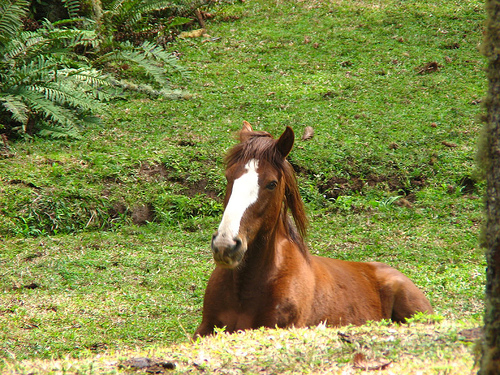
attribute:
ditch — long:
[85, 257, 494, 366]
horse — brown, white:
[172, 103, 437, 340]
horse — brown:
[196, 121, 428, 338]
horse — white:
[184, 116, 436, 340]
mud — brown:
[67, 195, 154, 236]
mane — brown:
[238, 130, 315, 250]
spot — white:
[210, 154, 259, 257]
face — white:
[195, 130, 301, 283]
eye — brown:
[260, 177, 281, 194]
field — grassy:
[4, 4, 497, 373]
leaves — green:
[34, 77, 95, 104]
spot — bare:
[348, 108, 439, 206]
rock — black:
[117, 353, 179, 371]